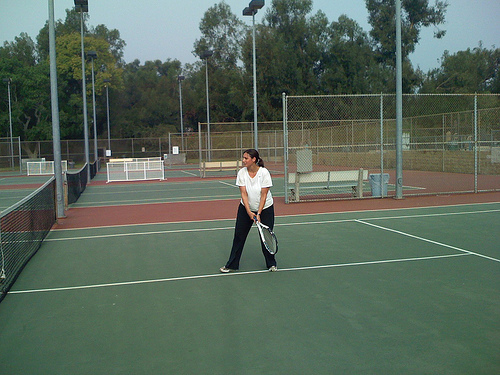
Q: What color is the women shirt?
A: White.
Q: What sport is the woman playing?
A: Tennis.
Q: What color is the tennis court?
A: Green.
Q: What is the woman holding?
A: A tennis racket.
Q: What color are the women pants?
A: Black.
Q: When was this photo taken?
A: Day time.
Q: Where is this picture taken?
A: A tennis court.